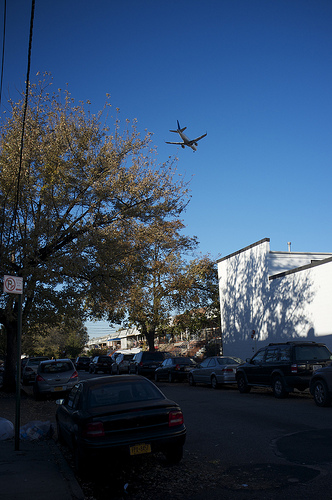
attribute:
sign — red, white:
[3, 274, 25, 295]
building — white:
[216, 237, 332, 364]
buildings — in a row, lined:
[81, 237, 331, 363]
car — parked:
[55, 373, 186, 468]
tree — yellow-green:
[0, 69, 217, 395]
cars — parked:
[20, 339, 331, 469]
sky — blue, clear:
[1, 0, 331, 341]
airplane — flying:
[166, 120, 208, 154]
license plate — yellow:
[128, 442, 153, 456]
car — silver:
[186, 354, 243, 388]